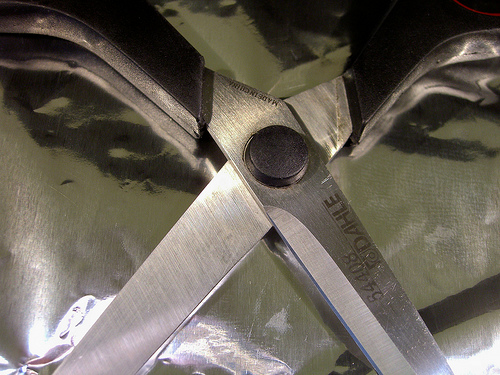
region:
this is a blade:
[18, 140, 293, 373]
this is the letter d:
[349, 229, 375, 257]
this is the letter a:
[337, 223, 367, 238]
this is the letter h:
[333, 205, 358, 230]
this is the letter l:
[320, 192, 347, 219]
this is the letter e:
[313, 190, 346, 210]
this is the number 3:
[362, 285, 390, 311]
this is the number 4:
[353, 274, 381, 296]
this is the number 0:
[346, 255, 368, 282]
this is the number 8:
[330, 243, 367, 270]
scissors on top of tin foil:
[9, 2, 475, 367]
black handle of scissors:
[15, 0, 215, 146]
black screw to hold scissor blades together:
[232, 113, 320, 193]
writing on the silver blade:
[301, 185, 393, 311]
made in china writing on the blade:
[212, 66, 292, 112]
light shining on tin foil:
[25, 272, 124, 368]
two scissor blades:
[71, 216, 441, 367]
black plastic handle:
[350, 0, 480, 138]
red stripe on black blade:
[445, 0, 489, 37]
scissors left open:
[27, 10, 469, 372]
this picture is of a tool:
[34, 28, 452, 342]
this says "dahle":
[307, 175, 383, 264]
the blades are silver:
[102, 205, 379, 312]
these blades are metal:
[115, 208, 412, 303]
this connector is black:
[223, 118, 341, 188]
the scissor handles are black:
[41, 5, 218, 107]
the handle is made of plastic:
[38, 14, 195, 116]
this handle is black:
[36, 3, 276, 110]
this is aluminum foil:
[15, 128, 154, 292]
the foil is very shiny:
[37, 236, 161, 361]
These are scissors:
[30, 203, 101, 283]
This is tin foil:
[35, 212, 70, 278]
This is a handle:
[138, 74, 157, 97]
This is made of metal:
[89, 119, 266, 341]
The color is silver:
[63, 234, 261, 367]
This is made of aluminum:
[106, 212, 123, 232]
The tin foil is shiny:
[63, 214, 127, 306]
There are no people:
[98, 244, 196, 331]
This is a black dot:
[240, 105, 323, 244]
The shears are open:
[223, 198, 411, 334]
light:
[457, 344, 493, 366]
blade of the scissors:
[146, 262, 211, 299]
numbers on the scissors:
[333, 249, 390, 303]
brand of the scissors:
[325, 190, 377, 254]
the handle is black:
[362, 24, 417, 74]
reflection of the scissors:
[39, 98, 130, 166]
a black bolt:
[248, 124, 308, 178]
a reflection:
[398, 107, 470, 161]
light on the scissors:
[211, 177, 240, 196]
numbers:
[336, 250, 391, 308]